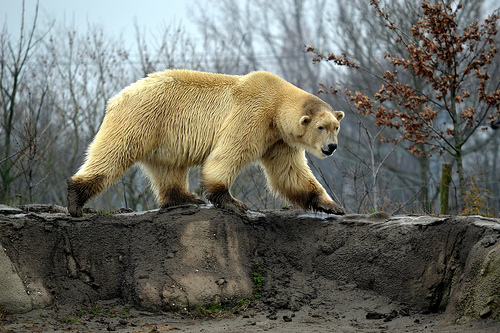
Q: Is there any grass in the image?
A: Yes, there is grass.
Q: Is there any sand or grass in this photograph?
A: Yes, there is grass.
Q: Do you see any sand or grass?
A: Yes, there is grass.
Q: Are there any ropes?
A: No, there are no ropes.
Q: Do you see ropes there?
A: No, there are no ropes.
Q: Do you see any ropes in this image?
A: No, there are no ropes.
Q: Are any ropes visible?
A: No, there are no ropes.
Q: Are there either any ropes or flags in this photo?
A: No, there are no ropes or flags.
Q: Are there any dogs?
A: No, there are no dogs.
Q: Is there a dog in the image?
A: No, there are no dogs.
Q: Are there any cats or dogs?
A: No, there are no dogs or cats.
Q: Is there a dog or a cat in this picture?
A: No, there are no dogs or cats.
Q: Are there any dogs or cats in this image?
A: No, there are no dogs or cats.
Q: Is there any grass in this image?
A: Yes, there is grass.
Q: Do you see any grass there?
A: Yes, there is grass.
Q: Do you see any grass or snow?
A: Yes, there is grass.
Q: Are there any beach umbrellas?
A: No, there are no beach umbrellas.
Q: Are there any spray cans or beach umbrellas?
A: No, there are no beach umbrellas or spray cans.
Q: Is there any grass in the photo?
A: Yes, there is grass.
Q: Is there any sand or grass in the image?
A: Yes, there is grass.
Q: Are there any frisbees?
A: No, there are no frisbees.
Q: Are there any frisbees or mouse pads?
A: No, there are no frisbees or mouse pads.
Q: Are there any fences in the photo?
A: Yes, there is a fence.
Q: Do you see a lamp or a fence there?
A: Yes, there is a fence.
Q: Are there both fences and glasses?
A: No, there is a fence but no glasses.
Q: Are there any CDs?
A: No, there are no cds.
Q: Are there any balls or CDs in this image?
A: No, there are no CDs or balls.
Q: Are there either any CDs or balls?
A: No, there are no CDs or balls.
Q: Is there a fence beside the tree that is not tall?
A: Yes, there is a fence beside the tree.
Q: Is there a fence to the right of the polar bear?
A: Yes, there is a fence to the right of the polar bear.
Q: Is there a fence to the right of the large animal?
A: Yes, there is a fence to the right of the polar bear.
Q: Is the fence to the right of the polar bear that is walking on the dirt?
A: Yes, the fence is to the right of the polar bear.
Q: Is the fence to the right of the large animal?
A: Yes, the fence is to the right of the polar bear.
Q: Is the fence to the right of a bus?
A: No, the fence is to the right of the polar bear.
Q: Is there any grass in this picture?
A: Yes, there is grass.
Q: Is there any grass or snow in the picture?
A: Yes, there is grass.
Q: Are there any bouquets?
A: No, there are no bouquets.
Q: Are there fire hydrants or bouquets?
A: No, there are no bouquets or fire hydrants.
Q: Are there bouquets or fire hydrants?
A: No, there are no bouquets or fire hydrants.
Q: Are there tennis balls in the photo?
A: No, there are no tennis balls.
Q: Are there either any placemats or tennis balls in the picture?
A: No, there are no tennis balls or placemats.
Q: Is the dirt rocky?
A: Yes, the dirt is rocky.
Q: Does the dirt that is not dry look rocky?
A: Yes, the dirt is rocky.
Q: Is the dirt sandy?
A: No, the dirt is rocky.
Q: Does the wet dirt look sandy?
A: No, the dirt is rocky.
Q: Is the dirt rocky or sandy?
A: The dirt is rocky.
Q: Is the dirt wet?
A: Yes, the dirt is wet.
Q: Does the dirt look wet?
A: Yes, the dirt is wet.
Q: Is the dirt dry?
A: No, the dirt is wet.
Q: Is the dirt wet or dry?
A: The dirt is wet.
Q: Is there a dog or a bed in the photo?
A: No, there are no dogs or beds.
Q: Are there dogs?
A: No, there are no dogs.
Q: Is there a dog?
A: No, there are no dogs.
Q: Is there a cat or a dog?
A: No, there are no dogs or cats.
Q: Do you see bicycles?
A: No, there are no bicycles.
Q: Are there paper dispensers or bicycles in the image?
A: No, there are no bicycles or paper dispensers.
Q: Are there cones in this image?
A: No, there are no cones.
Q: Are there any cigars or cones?
A: No, there are no cones or cigars.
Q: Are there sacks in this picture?
A: No, there are no sacks.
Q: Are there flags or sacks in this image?
A: No, there are no sacks or flags.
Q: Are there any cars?
A: No, there are no cars.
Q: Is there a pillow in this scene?
A: No, there are no pillows.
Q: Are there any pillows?
A: No, there are no pillows.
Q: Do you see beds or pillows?
A: No, there are no pillows or beds.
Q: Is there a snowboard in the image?
A: No, there are no snowboards.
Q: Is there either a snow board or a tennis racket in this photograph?
A: No, there are no snowboards or rackets.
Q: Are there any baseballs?
A: No, there are no baseballs.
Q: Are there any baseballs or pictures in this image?
A: No, there are no baseballs or pictures.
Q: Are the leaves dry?
A: Yes, the leaves are dry.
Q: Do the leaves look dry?
A: Yes, the leaves are dry.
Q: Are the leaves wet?
A: No, the leaves are dry.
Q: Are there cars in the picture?
A: No, there are no cars.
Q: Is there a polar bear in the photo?
A: Yes, there is a polar bear.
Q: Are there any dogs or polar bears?
A: Yes, there is a polar bear.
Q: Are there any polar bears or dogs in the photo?
A: Yes, there is a polar bear.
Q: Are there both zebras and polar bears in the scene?
A: No, there is a polar bear but no zebras.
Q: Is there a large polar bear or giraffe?
A: Yes, there is a large polar bear.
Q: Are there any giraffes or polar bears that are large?
A: Yes, the polar bear is large.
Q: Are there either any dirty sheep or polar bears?
A: Yes, there is a dirty polar bear.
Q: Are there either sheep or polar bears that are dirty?
A: Yes, the polar bear is dirty.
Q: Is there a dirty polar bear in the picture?
A: Yes, there is a dirty polar bear.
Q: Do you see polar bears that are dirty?
A: Yes, there is a polar bear that is dirty.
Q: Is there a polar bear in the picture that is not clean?
A: Yes, there is a dirty polar bear.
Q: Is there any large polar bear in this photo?
A: Yes, there is a large polar bear.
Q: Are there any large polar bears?
A: Yes, there is a large polar bear.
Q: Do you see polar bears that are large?
A: Yes, there is a polar bear that is large.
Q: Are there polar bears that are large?
A: Yes, there is a polar bear that is large.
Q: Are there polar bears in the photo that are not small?
A: Yes, there is a large polar bear.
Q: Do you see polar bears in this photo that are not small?
A: Yes, there is a large polar bear.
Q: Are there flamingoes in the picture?
A: No, there are no flamingoes.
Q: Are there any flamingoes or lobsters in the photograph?
A: No, there are no flamingoes or lobsters.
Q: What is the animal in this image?
A: The animal is a polar bear.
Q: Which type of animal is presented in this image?
A: The animal is a polar bear.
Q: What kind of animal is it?
A: The animal is a polar bear.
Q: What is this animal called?
A: This is a polar bear.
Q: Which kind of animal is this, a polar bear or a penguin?
A: This is a polar bear.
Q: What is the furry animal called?
A: The animal is a polar bear.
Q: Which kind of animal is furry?
A: The animal is a polar bear.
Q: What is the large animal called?
A: The animal is a polar bear.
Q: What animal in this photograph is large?
A: The animal is a polar bear.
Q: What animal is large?
A: The animal is a polar bear.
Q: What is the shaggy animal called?
A: The animal is a polar bear.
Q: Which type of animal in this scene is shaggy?
A: The animal is a polar bear.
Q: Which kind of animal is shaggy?
A: The animal is a polar bear.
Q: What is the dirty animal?
A: The animal is a polar bear.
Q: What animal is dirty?
A: The animal is a polar bear.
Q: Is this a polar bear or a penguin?
A: This is a polar bear.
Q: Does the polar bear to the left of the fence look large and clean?
A: No, the polar bear is large but dirty.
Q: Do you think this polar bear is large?
A: Yes, the polar bear is large.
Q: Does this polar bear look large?
A: Yes, the polar bear is large.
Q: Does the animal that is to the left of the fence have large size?
A: Yes, the polar bear is large.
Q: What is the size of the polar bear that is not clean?
A: The polar bear is large.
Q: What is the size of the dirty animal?
A: The polar bear is large.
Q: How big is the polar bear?
A: The polar bear is large.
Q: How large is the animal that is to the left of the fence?
A: The polar bear is large.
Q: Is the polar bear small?
A: No, the polar bear is large.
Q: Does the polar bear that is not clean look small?
A: No, the polar bear is large.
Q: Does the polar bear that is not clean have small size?
A: No, the polar bear is large.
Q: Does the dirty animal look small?
A: No, the polar bear is large.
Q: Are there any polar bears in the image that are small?
A: No, there is a polar bear but it is large.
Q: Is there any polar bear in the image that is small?
A: No, there is a polar bear but it is large.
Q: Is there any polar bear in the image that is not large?
A: No, there is a polar bear but it is large.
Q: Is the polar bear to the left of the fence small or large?
A: The polar bear is large.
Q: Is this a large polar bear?
A: Yes, this is a large polar bear.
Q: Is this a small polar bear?
A: No, this is a large polar bear.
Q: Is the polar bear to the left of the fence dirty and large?
A: Yes, the polar bear is dirty and large.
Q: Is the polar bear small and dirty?
A: No, the polar bear is dirty but large.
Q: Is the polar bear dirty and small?
A: No, the polar bear is dirty but large.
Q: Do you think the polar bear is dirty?
A: Yes, the polar bear is dirty.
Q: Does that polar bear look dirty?
A: Yes, the polar bear is dirty.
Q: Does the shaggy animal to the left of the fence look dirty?
A: Yes, the polar bear is dirty.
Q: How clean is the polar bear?
A: The polar bear is dirty.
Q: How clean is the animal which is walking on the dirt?
A: The polar bear is dirty.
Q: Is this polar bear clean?
A: No, the polar bear is dirty.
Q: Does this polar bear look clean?
A: No, the polar bear is dirty.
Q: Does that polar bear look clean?
A: No, the polar bear is dirty.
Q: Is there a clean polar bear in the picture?
A: No, there is a polar bear but it is dirty.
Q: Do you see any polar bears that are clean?
A: No, there is a polar bear but it is dirty.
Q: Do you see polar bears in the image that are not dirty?
A: No, there is a polar bear but it is dirty.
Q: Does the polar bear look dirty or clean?
A: The polar bear is dirty.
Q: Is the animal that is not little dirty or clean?
A: The polar bear is dirty.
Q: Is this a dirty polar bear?
A: Yes, this is a dirty polar bear.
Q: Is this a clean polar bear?
A: No, this is a dirty polar bear.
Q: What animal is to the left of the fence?
A: The animal is a polar bear.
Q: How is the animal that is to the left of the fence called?
A: The animal is a polar bear.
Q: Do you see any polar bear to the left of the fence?
A: Yes, there is a polar bear to the left of the fence.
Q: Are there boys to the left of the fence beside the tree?
A: No, there is a polar bear to the left of the fence.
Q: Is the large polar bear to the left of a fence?
A: Yes, the polar bear is to the left of a fence.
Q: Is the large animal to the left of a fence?
A: Yes, the polar bear is to the left of a fence.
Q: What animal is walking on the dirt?
A: The polar bear is walking on the dirt.